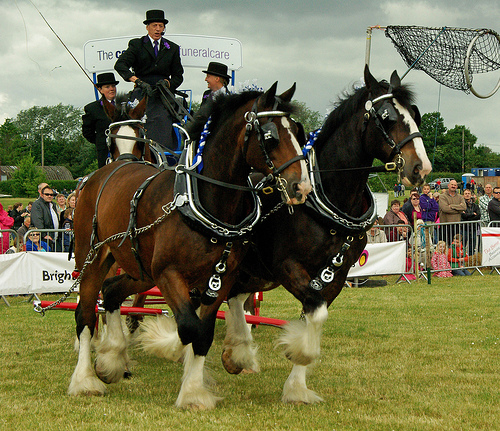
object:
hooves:
[66, 368, 110, 398]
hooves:
[92, 339, 127, 385]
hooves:
[174, 378, 218, 412]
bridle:
[173, 132, 265, 240]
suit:
[81, 95, 135, 169]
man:
[113, 6, 186, 166]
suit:
[113, 34, 184, 104]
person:
[79, 70, 131, 170]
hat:
[201, 61, 231, 79]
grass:
[0, 266, 500, 427]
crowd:
[366, 173, 500, 284]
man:
[29, 185, 62, 252]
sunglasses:
[44, 193, 54, 196]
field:
[0, 275, 500, 425]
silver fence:
[366, 218, 500, 285]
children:
[430, 239, 455, 277]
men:
[199, 61, 232, 106]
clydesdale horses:
[132, 61, 437, 410]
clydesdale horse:
[64, 77, 332, 416]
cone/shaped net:
[382, 23, 500, 100]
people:
[0, 201, 15, 253]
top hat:
[142, 8, 169, 25]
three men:
[81, 8, 234, 170]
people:
[55, 194, 66, 222]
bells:
[214, 259, 228, 274]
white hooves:
[221, 338, 262, 377]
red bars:
[38, 299, 290, 326]